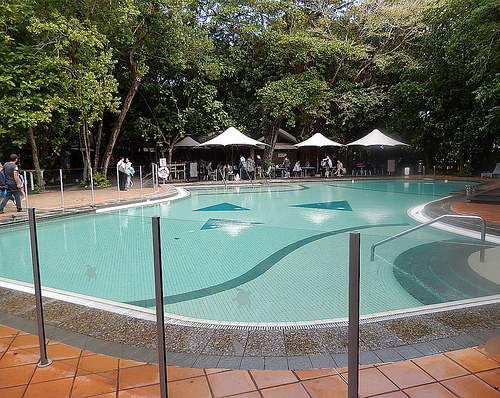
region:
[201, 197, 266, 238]
traigle shapes are on the floor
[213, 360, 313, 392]
the tiles are brown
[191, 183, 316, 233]
the water is blue in color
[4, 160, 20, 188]
the shirt is grey in color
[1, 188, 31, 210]
the pants are grey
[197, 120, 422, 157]
the umbrelas are three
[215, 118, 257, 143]
the umbrella is white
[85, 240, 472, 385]
the barricade is made of glass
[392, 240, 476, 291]
steps are in the swimming pool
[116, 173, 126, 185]
the pants are black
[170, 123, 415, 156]
white umbrellas by the pool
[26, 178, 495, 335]
a swimming pool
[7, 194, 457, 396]
a fence around the swimming pool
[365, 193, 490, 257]
a silver bar in the pool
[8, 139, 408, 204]
people standing around the pool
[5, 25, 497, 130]
trees around the pool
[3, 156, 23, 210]
a person wearing a black shirt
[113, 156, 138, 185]
two people standing on the other side of the fence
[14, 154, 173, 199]
a chain link fence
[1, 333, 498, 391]
red tile in front of the pool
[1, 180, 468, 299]
pool outside on lawn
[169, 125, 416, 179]
umbrellas on seating areas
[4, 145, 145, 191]
people on the sidewalk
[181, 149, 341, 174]
people in seating area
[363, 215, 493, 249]
rail going into water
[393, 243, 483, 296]
steps to the pool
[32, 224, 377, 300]
water in the pool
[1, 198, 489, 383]
glass wall circling pool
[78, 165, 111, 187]
plants on the ground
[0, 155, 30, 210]
man walking on sidewalk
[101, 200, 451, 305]
A beautiful swimming pool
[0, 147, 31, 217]
A person around the swiming pool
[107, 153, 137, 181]
A person around the swiming pool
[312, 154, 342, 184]
A person around the swiming pool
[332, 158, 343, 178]
A person around the swiming pool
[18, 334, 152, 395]
A smooth swimming pavement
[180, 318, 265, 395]
A smooth swimming pavement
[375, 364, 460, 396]
A smooth swimming pavement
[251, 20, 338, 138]
Thick green tree leaves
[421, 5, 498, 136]
Thick green tree leaves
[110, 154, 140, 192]
person standing near pool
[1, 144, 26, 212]
person wearing a shirt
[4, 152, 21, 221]
person wearing blue jeans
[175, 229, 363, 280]
a body of pool water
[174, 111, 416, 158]
white tents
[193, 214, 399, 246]
reflections from the pool water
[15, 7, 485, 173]
bunch of trees near the pool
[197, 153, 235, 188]
person sitting on chair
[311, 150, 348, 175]
person sitting on a chair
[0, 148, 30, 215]
person walking near by pool